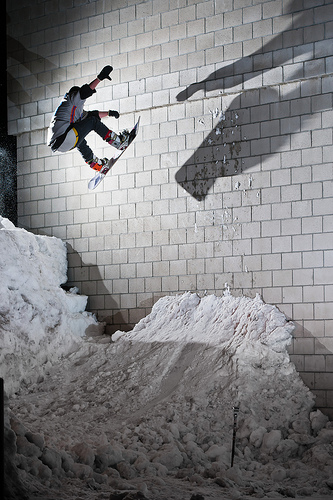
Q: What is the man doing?
A: Snowboarding.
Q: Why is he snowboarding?
A: For sport.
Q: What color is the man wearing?
A: White.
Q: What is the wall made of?
A: Brick.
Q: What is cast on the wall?
A: A shadow.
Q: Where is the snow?
A: On the ground.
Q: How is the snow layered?
A: It is in clumps.